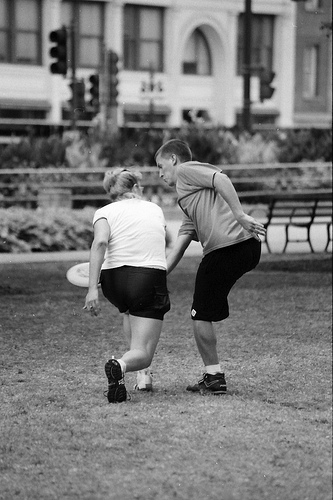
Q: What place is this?
A: It is a field.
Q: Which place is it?
A: It is a field.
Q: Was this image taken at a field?
A: Yes, it was taken in a field.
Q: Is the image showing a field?
A: Yes, it is showing a field.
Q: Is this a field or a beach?
A: It is a field.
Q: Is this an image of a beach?
A: No, the picture is showing a field.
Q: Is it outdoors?
A: Yes, it is outdoors.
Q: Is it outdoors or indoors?
A: It is outdoors.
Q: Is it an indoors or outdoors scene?
A: It is outdoors.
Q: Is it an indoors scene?
A: No, it is outdoors.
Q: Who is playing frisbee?
A: The man is playing frisbee.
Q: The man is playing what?
A: The man is playing frisbee.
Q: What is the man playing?
A: The man is playing frisbee.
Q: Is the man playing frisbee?
A: Yes, the man is playing frisbee.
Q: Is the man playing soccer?
A: No, the man is playing frisbee.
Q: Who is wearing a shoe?
A: The man is wearing a shoe.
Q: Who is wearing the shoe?
A: The man is wearing a shoe.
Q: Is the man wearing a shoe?
A: Yes, the man is wearing a shoe.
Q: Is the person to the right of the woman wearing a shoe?
A: Yes, the man is wearing a shoe.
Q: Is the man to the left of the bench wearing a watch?
A: No, the man is wearing a shoe.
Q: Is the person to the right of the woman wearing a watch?
A: No, the man is wearing a shoe.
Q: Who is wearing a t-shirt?
A: The man is wearing a t-shirt.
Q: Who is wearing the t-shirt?
A: The man is wearing a t-shirt.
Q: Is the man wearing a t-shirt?
A: Yes, the man is wearing a t-shirt.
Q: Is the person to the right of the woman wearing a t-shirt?
A: Yes, the man is wearing a t-shirt.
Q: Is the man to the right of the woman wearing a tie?
A: No, the man is wearing a t-shirt.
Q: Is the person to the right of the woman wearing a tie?
A: No, the man is wearing a t-shirt.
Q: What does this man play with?
A: The man plays with a frisbee.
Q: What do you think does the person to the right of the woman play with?
A: The man plays with a frisbee.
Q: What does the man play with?
A: The man plays with a frisbee.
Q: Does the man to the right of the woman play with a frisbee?
A: Yes, the man plays with a frisbee.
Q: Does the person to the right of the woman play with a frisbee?
A: Yes, the man plays with a frisbee.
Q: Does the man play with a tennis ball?
A: No, the man plays with a frisbee.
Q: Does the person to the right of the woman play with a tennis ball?
A: No, the man plays with a frisbee.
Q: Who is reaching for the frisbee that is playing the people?
A: The man is reaching for the frisbee.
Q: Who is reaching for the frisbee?
A: The man is reaching for the frisbee.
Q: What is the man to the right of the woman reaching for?
A: The man is reaching for the frisbee.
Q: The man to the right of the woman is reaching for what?
A: The man is reaching for the frisbee.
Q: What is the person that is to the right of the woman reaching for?
A: The man is reaching for the frisbee.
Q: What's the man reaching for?
A: The man is reaching for the frisbee.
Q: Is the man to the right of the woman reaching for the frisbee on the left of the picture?
A: Yes, the man is reaching for the frisbee.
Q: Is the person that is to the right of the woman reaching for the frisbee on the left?
A: Yes, the man is reaching for the frisbee.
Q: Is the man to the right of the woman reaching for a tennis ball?
A: No, the man is reaching for the frisbee.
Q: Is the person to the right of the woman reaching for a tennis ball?
A: No, the man is reaching for the frisbee.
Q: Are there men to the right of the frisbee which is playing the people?
A: Yes, there is a man to the right of the frisbee.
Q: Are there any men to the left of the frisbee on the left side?
A: No, the man is to the right of the frisbee.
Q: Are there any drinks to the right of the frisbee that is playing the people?
A: No, there is a man to the right of the frisbee.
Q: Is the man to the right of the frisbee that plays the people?
A: Yes, the man is to the right of the frisbee.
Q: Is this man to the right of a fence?
A: No, the man is to the right of the frisbee.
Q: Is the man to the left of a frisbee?
A: No, the man is to the right of a frisbee.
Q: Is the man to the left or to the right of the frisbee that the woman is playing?
A: The man is to the right of the frisbee.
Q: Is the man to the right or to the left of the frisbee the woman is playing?
A: The man is to the right of the frisbee.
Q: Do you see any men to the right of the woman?
A: Yes, there is a man to the right of the woman.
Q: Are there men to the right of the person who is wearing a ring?
A: Yes, there is a man to the right of the woman.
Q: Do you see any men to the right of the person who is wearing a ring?
A: Yes, there is a man to the right of the woman.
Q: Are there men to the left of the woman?
A: No, the man is to the right of the woman.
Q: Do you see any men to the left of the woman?
A: No, the man is to the right of the woman.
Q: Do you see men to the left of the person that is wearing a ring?
A: No, the man is to the right of the woman.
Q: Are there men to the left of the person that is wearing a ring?
A: No, the man is to the right of the woman.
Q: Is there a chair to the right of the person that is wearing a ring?
A: No, there is a man to the right of the woman.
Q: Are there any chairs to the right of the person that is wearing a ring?
A: No, there is a man to the right of the woman.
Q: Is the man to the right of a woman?
A: Yes, the man is to the right of a woman.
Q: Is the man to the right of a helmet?
A: No, the man is to the right of a woman.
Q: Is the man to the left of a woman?
A: No, the man is to the right of a woman.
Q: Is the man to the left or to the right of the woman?
A: The man is to the right of the woman.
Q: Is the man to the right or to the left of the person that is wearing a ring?
A: The man is to the right of the woman.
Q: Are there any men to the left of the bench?
A: Yes, there is a man to the left of the bench.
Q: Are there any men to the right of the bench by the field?
A: No, the man is to the left of the bench.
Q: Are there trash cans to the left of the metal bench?
A: No, there is a man to the left of the bench.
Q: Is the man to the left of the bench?
A: Yes, the man is to the left of the bench.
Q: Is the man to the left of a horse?
A: No, the man is to the left of the bench.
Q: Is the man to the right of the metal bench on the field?
A: No, the man is to the left of the bench.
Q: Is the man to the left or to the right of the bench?
A: The man is to the left of the bench.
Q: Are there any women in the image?
A: Yes, there is a woman.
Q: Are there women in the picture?
A: Yes, there is a woman.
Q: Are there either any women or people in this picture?
A: Yes, there is a woman.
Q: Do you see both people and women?
A: Yes, there are both a woman and people.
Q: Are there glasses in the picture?
A: No, there are no glasses.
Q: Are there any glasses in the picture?
A: No, there are no glasses.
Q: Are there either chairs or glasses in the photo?
A: No, there are no glasses or chairs.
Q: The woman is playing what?
A: The woman is playing frisbee.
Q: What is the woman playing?
A: The woman is playing frisbee.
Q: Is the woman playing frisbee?
A: Yes, the woman is playing frisbee.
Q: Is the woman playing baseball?
A: No, the woman is playing frisbee.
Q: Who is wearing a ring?
A: The woman is wearing a ring.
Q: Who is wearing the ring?
A: The woman is wearing a ring.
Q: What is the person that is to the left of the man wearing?
A: The woman is wearing a ring.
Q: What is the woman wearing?
A: The woman is wearing a ring.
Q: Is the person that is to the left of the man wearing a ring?
A: Yes, the woman is wearing a ring.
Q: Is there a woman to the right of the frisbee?
A: Yes, there is a woman to the right of the frisbee.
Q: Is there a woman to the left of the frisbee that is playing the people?
A: No, the woman is to the right of the frisbee.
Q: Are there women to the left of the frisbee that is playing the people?
A: No, the woman is to the right of the frisbee.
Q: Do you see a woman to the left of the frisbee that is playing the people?
A: No, the woman is to the right of the frisbee.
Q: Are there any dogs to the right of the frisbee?
A: No, there is a woman to the right of the frisbee.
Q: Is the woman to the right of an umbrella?
A: No, the woman is to the right of a frisbee.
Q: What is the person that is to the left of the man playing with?
A: The woman is playing with a frisbee.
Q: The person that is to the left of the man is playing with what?
A: The woman is playing with a frisbee.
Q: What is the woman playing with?
A: The woman is playing with a frisbee.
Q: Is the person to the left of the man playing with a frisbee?
A: Yes, the woman is playing with a frisbee.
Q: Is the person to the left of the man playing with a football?
A: No, the woman is playing with a frisbee.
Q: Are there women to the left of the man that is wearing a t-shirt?
A: Yes, there is a woman to the left of the man.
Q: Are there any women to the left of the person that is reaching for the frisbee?
A: Yes, there is a woman to the left of the man.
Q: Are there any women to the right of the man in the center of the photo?
A: No, the woman is to the left of the man.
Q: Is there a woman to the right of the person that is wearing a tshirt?
A: No, the woman is to the left of the man.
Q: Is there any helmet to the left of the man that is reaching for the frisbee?
A: No, there is a woman to the left of the man.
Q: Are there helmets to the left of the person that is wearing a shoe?
A: No, there is a woman to the left of the man.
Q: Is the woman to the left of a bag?
A: No, the woman is to the left of the man.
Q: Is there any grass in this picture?
A: Yes, there is grass.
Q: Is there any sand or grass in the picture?
A: Yes, there is grass.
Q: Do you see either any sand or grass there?
A: Yes, there is grass.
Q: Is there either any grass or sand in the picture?
A: Yes, there is grass.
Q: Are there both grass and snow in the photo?
A: No, there is grass but no snow.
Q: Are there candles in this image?
A: No, there are no candles.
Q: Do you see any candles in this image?
A: No, there are no candles.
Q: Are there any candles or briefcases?
A: No, there are no candles or briefcases.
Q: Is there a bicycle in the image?
A: No, there are no bicycles.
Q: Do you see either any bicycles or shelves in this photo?
A: No, there are no bicycles or shelves.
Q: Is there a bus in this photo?
A: No, there are no buses.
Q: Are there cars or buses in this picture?
A: No, there are no buses or cars.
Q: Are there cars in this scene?
A: No, there are no cars.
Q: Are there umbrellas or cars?
A: No, there are no cars or umbrellas.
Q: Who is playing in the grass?
A: The people are playing in the grass.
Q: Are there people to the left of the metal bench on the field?
A: Yes, there are people to the left of the bench.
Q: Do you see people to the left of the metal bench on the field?
A: Yes, there are people to the left of the bench.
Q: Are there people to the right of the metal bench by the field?
A: No, the people are to the left of the bench.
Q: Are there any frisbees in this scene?
A: Yes, there is a frisbee.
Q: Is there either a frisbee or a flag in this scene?
A: Yes, there is a frisbee.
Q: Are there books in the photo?
A: No, there are no books.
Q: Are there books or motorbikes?
A: No, there are no books or motorbikes.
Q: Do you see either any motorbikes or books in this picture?
A: No, there are no books or motorbikes.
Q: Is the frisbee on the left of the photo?
A: Yes, the frisbee is on the left of the image.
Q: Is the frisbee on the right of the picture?
A: No, the frisbee is on the left of the image.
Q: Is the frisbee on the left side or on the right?
A: The frisbee is on the left of the image.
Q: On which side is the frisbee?
A: The frisbee is on the left of the image.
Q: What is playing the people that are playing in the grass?
A: The frisbee is playing the people.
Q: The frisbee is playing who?
A: The frisbee is playing the people.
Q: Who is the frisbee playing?
A: The frisbee is playing the people.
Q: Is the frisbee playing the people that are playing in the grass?
A: Yes, the frisbee is playing the people.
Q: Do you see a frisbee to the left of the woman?
A: Yes, there is a frisbee to the left of the woman.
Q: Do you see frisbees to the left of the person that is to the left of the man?
A: Yes, there is a frisbee to the left of the woman.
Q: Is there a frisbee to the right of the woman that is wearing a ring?
A: No, the frisbee is to the left of the woman.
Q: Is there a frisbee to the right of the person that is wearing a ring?
A: No, the frisbee is to the left of the woman.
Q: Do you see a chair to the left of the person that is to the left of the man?
A: No, there is a frisbee to the left of the woman.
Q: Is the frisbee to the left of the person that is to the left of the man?
A: Yes, the frisbee is to the left of the woman.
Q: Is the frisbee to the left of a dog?
A: No, the frisbee is to the left of the woman.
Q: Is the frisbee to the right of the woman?
A: No, the frisbee is to the left of the woman.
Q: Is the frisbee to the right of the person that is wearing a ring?
A: No, the frisbee is to the left of the woman.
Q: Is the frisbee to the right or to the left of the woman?
A: The frisbee is to the left of the woman.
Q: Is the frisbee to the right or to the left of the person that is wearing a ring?
A: The frisbee is to the left of the woman.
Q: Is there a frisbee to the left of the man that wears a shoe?
A: Yes, there is a frisbee to the left of the man.